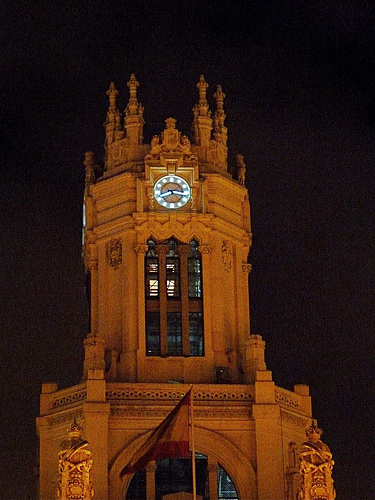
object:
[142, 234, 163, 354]
window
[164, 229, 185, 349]
window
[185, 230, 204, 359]
window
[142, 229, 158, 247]
pointed top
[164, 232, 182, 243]
pointed top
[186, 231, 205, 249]
pointed top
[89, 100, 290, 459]
wall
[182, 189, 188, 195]
3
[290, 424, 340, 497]
carved stone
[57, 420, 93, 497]
carved stone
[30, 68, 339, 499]
building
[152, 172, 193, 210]
clock face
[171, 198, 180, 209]
6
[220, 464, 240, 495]
window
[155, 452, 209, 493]
window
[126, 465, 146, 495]
window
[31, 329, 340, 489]
bottom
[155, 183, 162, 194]
9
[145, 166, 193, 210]
clock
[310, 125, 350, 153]
ground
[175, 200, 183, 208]
5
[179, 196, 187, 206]
number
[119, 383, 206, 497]
flag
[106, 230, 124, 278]
decorative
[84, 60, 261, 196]
spikes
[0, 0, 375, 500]
sky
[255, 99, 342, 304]
nighttime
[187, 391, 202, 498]
pole